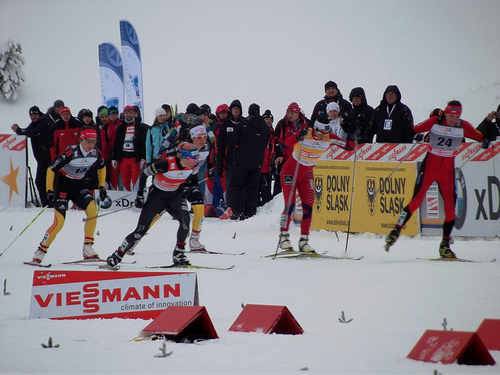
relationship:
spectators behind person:
[11, 80, 500, 220] [279, 114, 360, 254]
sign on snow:
[29, 270, 201, 319] [0, 176, 498, 375]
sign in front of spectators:
[310, 161, 420, 236] [11, 80, 500, 220]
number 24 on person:
[437, 136, 453, 148] [384, 100, 491, 258]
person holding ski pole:
[279, 114, 360, 254] [345, 133, 360, 254]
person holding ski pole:
[279, 114, 360, 254] [273, 133, 306, 259]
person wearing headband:
[32, 125, 108, 263] [78, 129, 99, 141]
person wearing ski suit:
[384, 100, 491, 258] [396, 114, 485, 243]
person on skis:
[384, 100, 491, 258] [417, 256, 498, 263]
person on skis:
[279, 114, 360, 254] [260, 251, 365, 261]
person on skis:
[127, 122, 217, 250] [184, 249, 246, 257]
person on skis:
[107, 143, 200, 268] [70, 262, 236, 272]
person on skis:
[32, 125, 108, 263] [22, 260, 139, 268]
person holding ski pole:
[32, 125, 108, 263] [0, 203, 49, 258]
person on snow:
[279, 114, 360, 254] [0, 176, 498, 375]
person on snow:
[107, 143, 200, 268] [0, 176, 498, 375]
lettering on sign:
[34, 282, 182, 313] [29, 270, 201, 319]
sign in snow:
[29, 270, 201, 319] [0, 176, 498, 375]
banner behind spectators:
[119, 20, 145, 124] [11, 80, 500, 220]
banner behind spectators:
[99, 41, 124, 118] [11, 80, 500, 220]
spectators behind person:
[11, 80, 500, 220] [127, 122, 217, 250]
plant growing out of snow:
[42, 336, 60, 349] [0, 176, 498, 375]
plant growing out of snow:
[154, 343, 174, 357] [0, 176, 498, 375]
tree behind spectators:
[1, 36, 27, 102] [11, 80, 500, 220]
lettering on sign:
[313, 165, 406, 229] [310, 161, 420, 236]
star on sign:
[0, 157, 21, 202] [0, 134, 27, 209]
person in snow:
[32, 125, 108, 263] [0, 176, 498, 375]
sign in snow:
[141, 306, 220, 339] [0, 176, 498, 375]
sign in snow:
[229, 304, 306, 335] [0, 176, 498, 375]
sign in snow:
[408, 328, 496, 365] [0, 176, 498, 375]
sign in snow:
[475, 318, 499, 350] [0, 176, 498, 375]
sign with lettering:
[310, 161, 420, 236] [313, 165, 406, 229]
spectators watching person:
[11, 80, 500, 220] [279, 114, 360, 254]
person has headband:
[127, 122, 217, 250] [188, 125, 206, 139]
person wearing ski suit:
[32, 125, 108, 263] [40, 144, 108, 249]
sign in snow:
[415, 161, 500, 239] [0, 176, 498, 375]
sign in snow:
[0, 134, 27, 209] [0, 176, 498, 375]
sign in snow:
[310, 161, 420, 236] [0, 176, 498, 375]